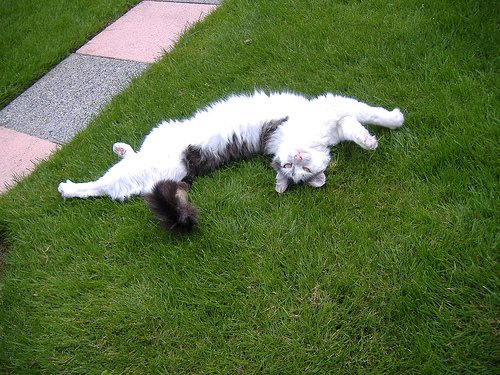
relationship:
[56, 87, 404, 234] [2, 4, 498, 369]
cat lying in grass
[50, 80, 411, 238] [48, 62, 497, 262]
cat laying in grass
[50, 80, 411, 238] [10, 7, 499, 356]
cat laying in a lawn